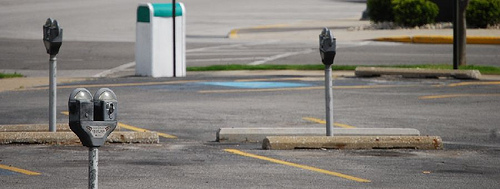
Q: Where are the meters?
A: In the parking lot.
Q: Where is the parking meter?
A: In the parking lot.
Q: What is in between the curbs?
A: Parking meters.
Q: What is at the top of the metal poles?
A: Parking meters.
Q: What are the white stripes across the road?
A: Crosswalk.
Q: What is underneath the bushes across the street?
A: Rocks.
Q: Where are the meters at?
A: Parking lot.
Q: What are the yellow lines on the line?
A: Parking spot markers.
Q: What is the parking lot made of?
A: Cement.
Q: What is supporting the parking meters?
A: Metal poles.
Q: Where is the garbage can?
A: On the sidewalk.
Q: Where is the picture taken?
A: Parking lot.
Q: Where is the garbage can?
A: In the parking lot.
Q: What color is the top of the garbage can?
A: Green.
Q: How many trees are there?
A: One.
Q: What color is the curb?
A: Yellow.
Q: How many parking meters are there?
A: Three.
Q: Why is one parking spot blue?
A: It is for handicapped only.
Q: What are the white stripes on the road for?
A: Cross walk.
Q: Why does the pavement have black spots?
A: It's dirty.